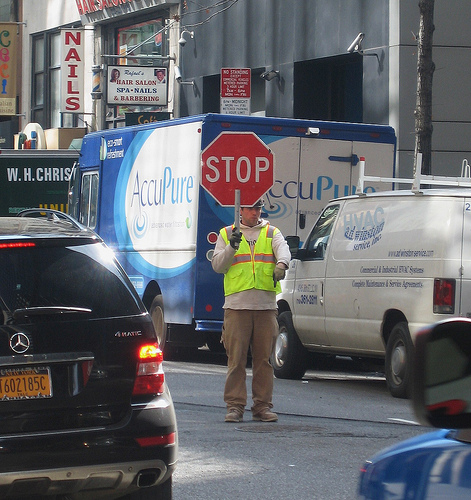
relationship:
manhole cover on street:
[231, 415, 327, 440] [179, 371, 363, 496]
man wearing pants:
[211, 195, 291, 422] [213, 296, 303, 392]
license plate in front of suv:
[0, 365, 53, 404] [0, 206, 178, 500]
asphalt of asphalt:
[258, 444, 329, 456] [159, 353, 442, 500]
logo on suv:
[122, 158, 195, 215] [0, 206, 178, 500]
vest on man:
[215, 220, 283, 291] [211, 201, 313, 433]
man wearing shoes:
[211, 196, 291, 422] [223, 403, 279, 422]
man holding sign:
[211, 196, 291, 422] [200, 129, 273, 247]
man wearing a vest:
[211, 196, 291, 422] [217, 220, 283, 298]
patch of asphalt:
[223, 436, 289, 495] [194, 428, 336, 489]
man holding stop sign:
[211, 196, 291, 422] [201, 131, 277, 207]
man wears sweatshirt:
[211, 195, 291, 422] [206, 218, 292, 310]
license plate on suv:
[0, 369, 54, 397] [0, 203, 178, 493]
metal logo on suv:
[7, 327, 31, 360] [0, 203, 178, 493]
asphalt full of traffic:
[159, 353, 442, 500] [12, 296, 219, 425]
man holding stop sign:
[211, 196, 291, 422] [173, 122, 275, 218]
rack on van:
[349, 151, 469, 196] [273, 160, 469, 410]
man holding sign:
[211, 195, 291, 422] [200, 131, 276, 209]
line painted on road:
[388, 415, 420, 429] [153, 352, 449, 498]